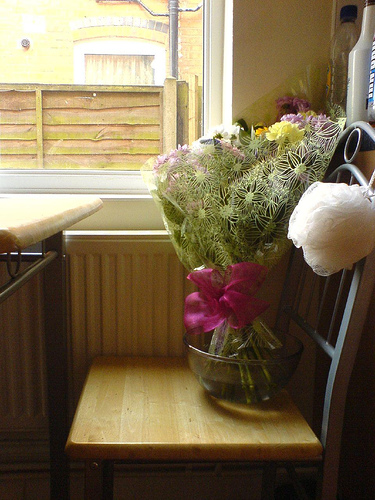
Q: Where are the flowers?
A: Bouquet.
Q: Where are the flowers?
A: Chari.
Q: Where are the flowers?
A: In water.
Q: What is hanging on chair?
A: Scrub.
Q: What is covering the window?
A: Blinds.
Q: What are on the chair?
A: Flowers.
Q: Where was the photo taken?
A: Inside a building.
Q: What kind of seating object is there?
A: A chair.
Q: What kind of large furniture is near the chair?
A: A table.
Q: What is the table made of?
A: Wood and metal.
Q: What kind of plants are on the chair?
A: Flowers.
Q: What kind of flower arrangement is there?
A: A bouquet.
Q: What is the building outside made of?
A: Bricks.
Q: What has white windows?
A: Brick building.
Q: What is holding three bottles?
A: Black shelf.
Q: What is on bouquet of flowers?
A: Pink bow.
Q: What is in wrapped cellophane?
A: A bouquet of flowers.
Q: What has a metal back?
A: A wooden chair.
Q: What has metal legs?
A: Wooden table.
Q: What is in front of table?
A: Window in wall.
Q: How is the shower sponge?
A: White mesh.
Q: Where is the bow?
A: Around flowers.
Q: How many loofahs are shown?
A: One.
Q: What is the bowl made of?
A: Glass.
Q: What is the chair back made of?
A: Iron.